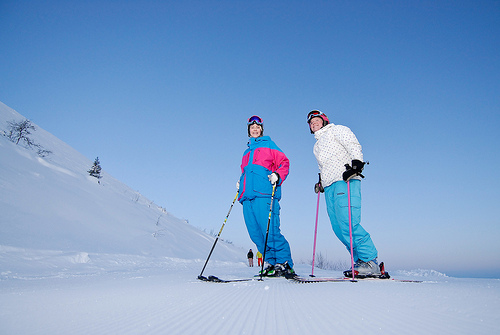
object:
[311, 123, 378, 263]
ski clothes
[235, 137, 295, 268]
ski clothes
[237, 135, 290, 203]
blue jacket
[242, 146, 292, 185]
pink stripe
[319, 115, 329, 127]
band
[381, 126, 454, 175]
ground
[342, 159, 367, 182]
gloves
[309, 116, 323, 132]
face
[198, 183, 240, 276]
pole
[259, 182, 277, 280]
pole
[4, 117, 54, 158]
brushes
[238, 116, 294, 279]
female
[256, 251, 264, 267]
person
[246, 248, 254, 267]
person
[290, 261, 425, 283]
skis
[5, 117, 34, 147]
tree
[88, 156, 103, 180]
pine tree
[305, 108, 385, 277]
female skier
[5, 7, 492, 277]
skies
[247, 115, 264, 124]
goggles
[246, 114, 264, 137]
heads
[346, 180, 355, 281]
poles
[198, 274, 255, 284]
snow ski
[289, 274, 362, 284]
snow ski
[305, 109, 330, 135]
head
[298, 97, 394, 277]
skier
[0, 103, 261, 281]
hill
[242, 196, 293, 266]
ski pants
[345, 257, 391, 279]
ski boots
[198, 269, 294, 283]
skis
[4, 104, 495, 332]
snow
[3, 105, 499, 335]
ski slope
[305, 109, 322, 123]
goggles